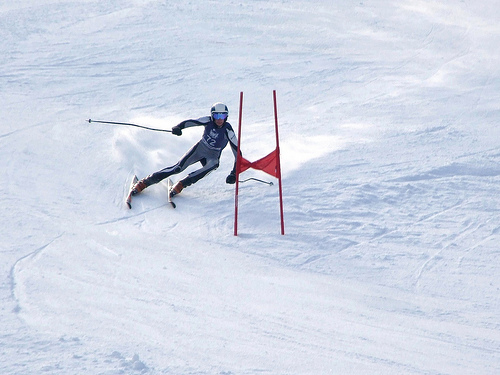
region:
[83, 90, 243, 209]
a professional skier competing in a skiing event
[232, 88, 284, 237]
a red flag marker on the snow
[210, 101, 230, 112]
a white and blue helmet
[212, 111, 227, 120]
blue goggles covering the skier's eyes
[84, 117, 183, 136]
a ski pole in the skier's right hand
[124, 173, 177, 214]
two snow skis on the skier's feet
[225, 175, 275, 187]
a ski pole in the skier's left hand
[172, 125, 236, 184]
winter gloves on the skier's hands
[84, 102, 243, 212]
a professional skier skiing on a snowy mountain slope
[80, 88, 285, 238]
a male skier skiing around a red flag marker on two poles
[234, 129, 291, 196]
red flag and post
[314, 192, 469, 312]
ski tracks in the snow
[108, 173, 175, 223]
two skis on the skier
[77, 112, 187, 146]
ski pole in right hand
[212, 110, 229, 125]
goggles being worn by skier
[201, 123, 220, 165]
number on person's shirt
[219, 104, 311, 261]
two poles holding red flag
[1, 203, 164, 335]
markings in the snow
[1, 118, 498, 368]
ground is covered in snow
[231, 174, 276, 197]
crooked ski pole in left hand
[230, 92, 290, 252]
The poles are red.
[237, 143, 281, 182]
The flag is red.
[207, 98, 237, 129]
The skier is wearing a helmet.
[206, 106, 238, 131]
The skier is wearing goggles.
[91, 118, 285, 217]
The ski poles are black.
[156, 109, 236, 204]
The snowsuit is black and grey.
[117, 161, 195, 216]
Skis on the person's feet.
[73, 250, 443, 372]
Snow on the ground.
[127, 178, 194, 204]
The shoes are brown.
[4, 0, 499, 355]
Taken during a competition.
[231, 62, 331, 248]
a red flag post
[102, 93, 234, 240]
a person skiing doen a hill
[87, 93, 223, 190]
snow being thrown by skier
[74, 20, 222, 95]
a white snow back ground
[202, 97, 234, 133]
person wearing helmet and goggles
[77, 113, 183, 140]
a ski pole in use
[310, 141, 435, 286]
tracks are in the snow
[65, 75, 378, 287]
a skier going around the post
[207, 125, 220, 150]
a number on the persons chest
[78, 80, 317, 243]
tilted skier going around red pole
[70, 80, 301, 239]
A man skiing the slalom.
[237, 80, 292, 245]
Red flags in the snow.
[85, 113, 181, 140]
A ski pole in a man's hand.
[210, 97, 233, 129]
A helmet on a man's head.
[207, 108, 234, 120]
Goggles on a man's face.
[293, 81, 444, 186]
Tracks in the snow.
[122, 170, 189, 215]
Orange skis on the ground.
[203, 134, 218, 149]
The number 72 on the chest.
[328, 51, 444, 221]
Large amounts of snow on the ground.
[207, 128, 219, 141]
Logo on the chest.